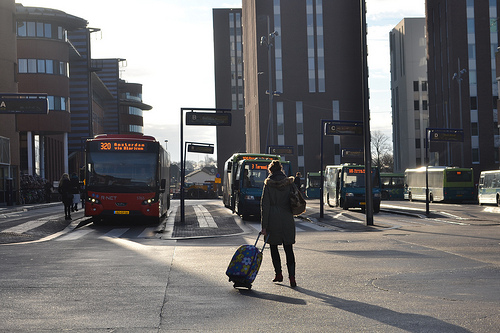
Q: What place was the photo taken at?
A: It was taken at the road.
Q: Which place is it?
A: It is a road.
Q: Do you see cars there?
A: No, there are no cars.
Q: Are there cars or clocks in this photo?
A: No, there are no cars or clocks.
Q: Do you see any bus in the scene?
A: Yes, there is a bus.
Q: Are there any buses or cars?
A: Yes, there is a bus.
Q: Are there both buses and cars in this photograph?
A: No, there is a bus but no cars.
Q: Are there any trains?
A: No, there are no trains.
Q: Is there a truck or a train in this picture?
A: No, there are no trains or trucks.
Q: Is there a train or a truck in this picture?
A: No, there are no trains or trucks.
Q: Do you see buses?
A: Yes, there is a bus.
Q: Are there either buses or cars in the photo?
A: Yes, there is a bus.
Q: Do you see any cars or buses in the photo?
A: Yes, there is a bus.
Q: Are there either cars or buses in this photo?
A: Yes, there is a bus.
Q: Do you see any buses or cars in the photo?
A: Yes, there is a bus.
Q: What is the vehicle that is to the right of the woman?
A: The vehicle is a bus.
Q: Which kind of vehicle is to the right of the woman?
A: The vehicle is a bus.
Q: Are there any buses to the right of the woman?
A: Yes, there is a bus to the right of the woman.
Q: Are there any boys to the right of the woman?
A: No, there is a bus to the right of the woman.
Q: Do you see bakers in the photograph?
A: No, there are no bakers.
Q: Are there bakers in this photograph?
A: No, there are no bakers.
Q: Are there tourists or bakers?
A: No, there are no bakers or tourists.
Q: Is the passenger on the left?
A: Yes, the passenger is on the left of the image.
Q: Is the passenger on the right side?
A: No, the passenger is on the left of the image.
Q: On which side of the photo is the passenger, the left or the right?
A: The passenger is on the left of the image.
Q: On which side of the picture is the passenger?
A: The passenger is on the left of the image.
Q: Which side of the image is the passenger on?
A: The passenger is on the left of the image.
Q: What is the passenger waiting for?
A: The passenger is waiting for the bus.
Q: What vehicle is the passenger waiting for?
A: The passenger is waiting for the bus.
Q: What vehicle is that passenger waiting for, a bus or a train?
A: The passenger is waiting for a bus.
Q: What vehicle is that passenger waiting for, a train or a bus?
A: The passenger is waiting for a bus.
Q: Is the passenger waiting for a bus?
A: Yes, the passenger is waiting for a bus.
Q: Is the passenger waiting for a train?
A: No, the passenger is waiting for a bus.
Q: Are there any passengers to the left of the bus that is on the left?
A: Yes, there is a passenger to the left of the bus.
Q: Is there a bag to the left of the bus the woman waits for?
A: No, there is a passenger to the left of the bus.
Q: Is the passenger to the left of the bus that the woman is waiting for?
A: Yes, the passenger is to the left of the bus.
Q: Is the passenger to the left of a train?
A: No, the passenger is to the left of the bus.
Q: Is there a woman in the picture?
A: Yes, there is a woman.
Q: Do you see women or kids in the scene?
A: Yes, there is a woman.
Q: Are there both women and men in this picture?
A: No, there is a woman but no men.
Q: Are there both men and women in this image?
A: No, there is a woman but no men.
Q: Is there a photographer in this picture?
A: No, there are no photographers.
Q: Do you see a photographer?
A: No, there are no photographers.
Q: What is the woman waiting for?
A: The woman is waiting for the bus.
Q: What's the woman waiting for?
A: The woman is waiting for the bus.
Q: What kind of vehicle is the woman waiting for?
A: The woman is waiting for the bus.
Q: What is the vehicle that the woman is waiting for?
A: The vehicle is a bus.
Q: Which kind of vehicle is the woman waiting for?
A: The woman is waiting for the bus.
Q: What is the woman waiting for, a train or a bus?
A: The woman is waiting for a bus.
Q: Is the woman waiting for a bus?
A: Yes, the woman is waiting for a bus.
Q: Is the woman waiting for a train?
A: No, the woman is waiting for a bus.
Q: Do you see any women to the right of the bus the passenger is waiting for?
A: Yes, there is a woman to the right of the bus.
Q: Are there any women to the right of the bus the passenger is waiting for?
A: Yes, there is a woman to the right of the bus.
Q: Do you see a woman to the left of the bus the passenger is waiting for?
A: No, the woman is to the right of the bus.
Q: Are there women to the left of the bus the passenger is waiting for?
A: No, the woman is to the right of the bus.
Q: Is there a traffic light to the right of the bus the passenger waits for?
A: No, there is a woman to the right of the bus.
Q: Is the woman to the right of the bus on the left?
A: Yes, the woman is to the right of the bus.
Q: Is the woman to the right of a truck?
A: No, the woman is to the right of the bus.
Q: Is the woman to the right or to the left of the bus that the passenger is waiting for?
A: The woman is to the right of the bus.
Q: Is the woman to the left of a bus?
A: Yes, the woman is to the left of a bus.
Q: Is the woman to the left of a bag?
A: No, the woman is to the left of a bus.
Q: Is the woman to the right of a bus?
A: No, the woman is to the left of a bus.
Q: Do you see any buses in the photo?
A: Yes, there is a bus.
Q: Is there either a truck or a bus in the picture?
A: Yes, there is a bus.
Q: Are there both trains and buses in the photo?
A: No, there is a bus but no trains.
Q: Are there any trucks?
A: No, there are no trucks.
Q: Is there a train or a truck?
A: No, there are no trucks or trains.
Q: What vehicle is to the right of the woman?
A: The vehicle is a bus.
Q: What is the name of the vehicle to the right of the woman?
A: The vehicle is a bus.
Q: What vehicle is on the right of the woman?
A: The vehicle is a bus.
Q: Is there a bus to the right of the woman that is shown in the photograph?
A: Yes, there is a bus to the right of the woman.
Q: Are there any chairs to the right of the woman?
A: No, there is a bus to the right of the woman.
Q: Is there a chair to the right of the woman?
A: No, there is a bus to the right of the woman.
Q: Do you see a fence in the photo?
A: No, there are no fences.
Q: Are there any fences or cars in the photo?
A: No, there are no fences or cars.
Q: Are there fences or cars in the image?
A: No, there are no cars or fences.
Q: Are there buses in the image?
A: Yes, there is a bus.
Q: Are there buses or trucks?
A: Yes, there is a bus.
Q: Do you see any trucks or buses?
A: Yes, there is a bus.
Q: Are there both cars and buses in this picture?
A: No, there is a bus but no cars.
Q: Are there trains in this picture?
A: No, there are no trains.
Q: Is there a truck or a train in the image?
A: No, there are no trains or trucks.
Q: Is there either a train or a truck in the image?
A: No, there are no trains or trucks.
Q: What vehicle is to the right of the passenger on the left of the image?
A: The vehicle is a bus.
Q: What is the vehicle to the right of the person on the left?
A: The vehicle is a bus.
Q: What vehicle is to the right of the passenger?
A: The vehicle is a bus.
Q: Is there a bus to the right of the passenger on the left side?
A: Yes, there is a bus to the right of the passenger.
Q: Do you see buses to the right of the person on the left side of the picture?
A: Yes, there is a bus to the right of the passenger.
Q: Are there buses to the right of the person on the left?
A: Yes, there is a bus to the right of the passenger.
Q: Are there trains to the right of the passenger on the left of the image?
A: No, there is a bus to the right of the passenger.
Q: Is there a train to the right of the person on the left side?
A: No, there is a bus to the right of the passenger.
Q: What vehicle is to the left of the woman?
A: The vehicle is a bus.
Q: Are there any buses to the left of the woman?
A: Yes, there is a bus to the left of the woman.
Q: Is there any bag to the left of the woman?
A: No, there is a bus to the left of the woman.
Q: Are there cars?
A: No, there are no cars.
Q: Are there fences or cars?
A: No, there are no cars or fences.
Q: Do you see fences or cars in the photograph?
A: No, there are no cars or fences.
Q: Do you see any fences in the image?
A: No, there are no fences.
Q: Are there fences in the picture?
A: No, there are no fences.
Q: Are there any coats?
A: Yes, there is a coat.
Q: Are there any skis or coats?
A: Yes, there is a coat.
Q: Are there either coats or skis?
A: Yes, there is a coat.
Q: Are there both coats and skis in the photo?
A: No, there is a coat but no skis.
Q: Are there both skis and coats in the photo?
A: No, there is a coat but no skis.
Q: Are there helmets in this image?
A: No, there are no helmets.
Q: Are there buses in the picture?
A: Yes, there is a bus.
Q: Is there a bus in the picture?
A: Yes, there is a bus.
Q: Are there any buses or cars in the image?
A: Yes, there is a bus.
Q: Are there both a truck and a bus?
A: No, there is a bus but no trucks.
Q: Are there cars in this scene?
A: No, there are no cars.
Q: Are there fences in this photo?
A: No, there are no fences.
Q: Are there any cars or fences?
A: No, there are no fences or cars.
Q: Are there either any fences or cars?
A: No, there are no fences or cars.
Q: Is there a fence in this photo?
A: No, there are no fences.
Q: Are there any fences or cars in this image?
A: No, there are no fences or cars.